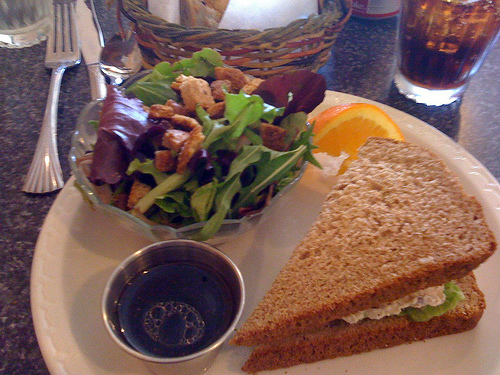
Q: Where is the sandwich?
A: On a plate.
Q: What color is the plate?
A: White.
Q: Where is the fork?
A: On the table.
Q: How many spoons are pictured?
A: One.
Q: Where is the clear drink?
A: Top left.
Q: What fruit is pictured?
A: An orange.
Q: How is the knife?
A: Between the fork and the spoon.